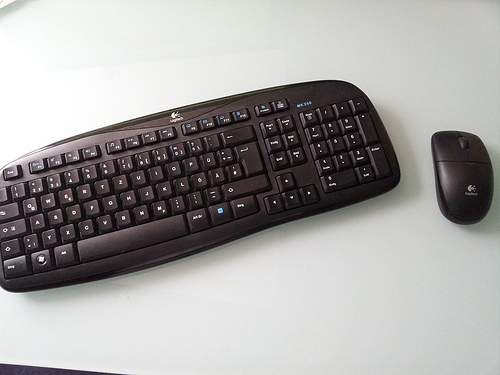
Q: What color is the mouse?
A: Black.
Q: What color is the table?
A: White.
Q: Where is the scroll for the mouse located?
A: Between the top two buttons.